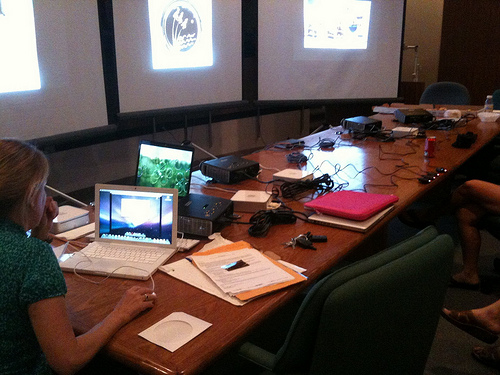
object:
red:
[303, 190, 399, 221]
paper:
[187, 247, 294, 295]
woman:
[2, 138, 155, 373]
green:
[1, 221, 69, 374]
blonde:
[1, 139, 50, 227]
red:
[423, 134, 443, 157]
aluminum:
[425, 134, 438, 156]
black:
[341, 115, 377, 128]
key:
[284, 236, 317, 254]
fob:
[309, 227, 327, 248]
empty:
[239, 216, 457, 373]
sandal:
[440, 303, 500, 346]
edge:
[418, 81, 473, 110]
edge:
[391, 100, 429, 110]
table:
[402, 78, 425, 105]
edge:
[305, 190, 399, 234]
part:
[55, 218, 97, 243]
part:
[27, 295, 75, 346]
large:
[56, 103, 499, 375]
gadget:
[416, 173, 432, 185]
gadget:
[283, 150, 310, 166]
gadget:
[317, 137, 337, 154]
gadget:
[450, 131, 478, 149]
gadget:
[397, 110, 435, 126]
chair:
[240, 225, 463, 375]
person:
[399, 178, 500, 291]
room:
[1, 0, 499, 373]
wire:
[373, 134, 419, 158]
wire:
[338, 170, 417, 196]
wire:
[245, 166, 279, 193]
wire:
[303, 134, 324, 153]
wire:
[189, 180, 241, 196]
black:
[191, 198, 209, 215]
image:
[302, 2, 370, 56]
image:
[146, 2, 219, 74]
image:
[4, 0, 44, 95]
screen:
[253, 0, 403, 97]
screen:
[105, 1, 249, 121]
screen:
[2, 1, 110, 145]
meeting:
[1, 141, 498, 349]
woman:
[440, 288, 500, 374]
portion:
[241, 166, 326, 198]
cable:
[246, 174, 289, 185]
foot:
[436, 301, 499, 346]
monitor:
[89, 181, 179, 246]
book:
[302, 190, 399, 223]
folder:
[195, 239, 306, 302]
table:
[36, 99, 496, 372]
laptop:
[61, 180, 177, 279]